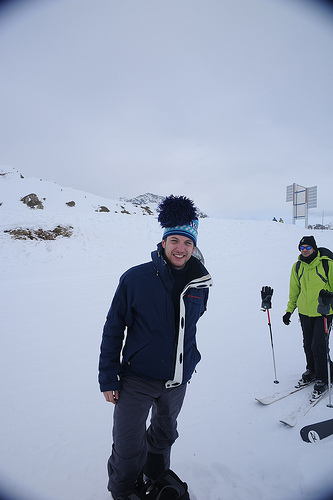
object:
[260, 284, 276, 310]
glove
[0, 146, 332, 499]
ground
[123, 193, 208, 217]
mountain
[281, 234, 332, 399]
skier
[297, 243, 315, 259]
face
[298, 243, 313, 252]
sunglasses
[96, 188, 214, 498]
skier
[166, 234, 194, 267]
face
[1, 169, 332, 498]
snow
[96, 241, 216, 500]
clothes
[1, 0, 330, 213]
sky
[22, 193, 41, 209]
rock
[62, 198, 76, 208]
rock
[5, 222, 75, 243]
bush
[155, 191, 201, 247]
hat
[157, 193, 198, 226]
topper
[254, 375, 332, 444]
ski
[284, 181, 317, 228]
sign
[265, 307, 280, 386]
ski pole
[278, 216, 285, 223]
tree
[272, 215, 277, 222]
tree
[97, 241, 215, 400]
jacket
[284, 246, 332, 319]
jacket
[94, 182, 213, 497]
person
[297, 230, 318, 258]
hat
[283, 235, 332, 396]
person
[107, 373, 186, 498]
pants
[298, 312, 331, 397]
pants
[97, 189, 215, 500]
man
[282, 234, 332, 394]
man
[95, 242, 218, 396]
ski jacket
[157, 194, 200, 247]
cap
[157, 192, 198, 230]
ball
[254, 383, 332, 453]
skis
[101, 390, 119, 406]
hand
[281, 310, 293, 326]
hand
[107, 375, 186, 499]
sweatpants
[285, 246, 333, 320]
sweater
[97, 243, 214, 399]
sweater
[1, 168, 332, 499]
hill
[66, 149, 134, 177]
clear